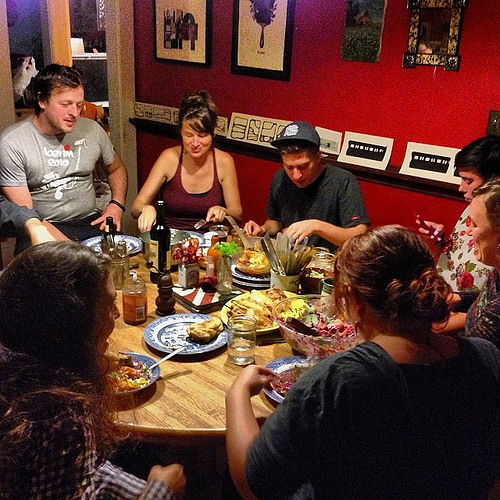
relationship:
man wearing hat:
[240, 118, 373, 257] [267, 120, 322, 148]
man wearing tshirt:
[4, 64, 129, 246] [1, 112, 117, 223]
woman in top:
[130, 89, 243, 235] [157, 140, 229, 235]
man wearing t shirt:
[4, 64, 129, 246] [1, 107, 123, 244]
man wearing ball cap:
[243, 118, 372, 258] [270, 121, 320, 149]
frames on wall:
[148, 2, 210, 67] [135, 0, 499, 271]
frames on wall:
[230, 1, 295, 77] [135, 0, 499, 271]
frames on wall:
[344, 1, 386, 60] [135, 0, 499, 271]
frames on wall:
[400, 2, 463, 70] [135, 0, 499, 271]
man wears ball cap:
[243, 118, 372, 258] [270, 121, 320, 149]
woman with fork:
[130, 90, 242, 232] [194, 217, 213, 230]